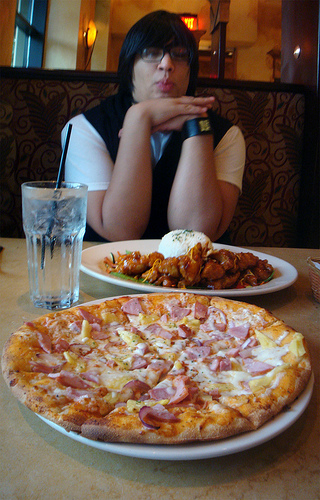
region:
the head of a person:
[119, 22, 229, 129]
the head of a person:
[110, 58, 192, 118]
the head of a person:
[128, 3, 196, 156]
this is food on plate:
[107, 234, 271, 286]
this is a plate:
[3, 293, 307, 468]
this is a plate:
[77, 230, 302, 293]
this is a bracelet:
[182, 115, 214, 140]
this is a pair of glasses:
[137, 38, 200, 64]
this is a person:
[64, 1, 245, 248]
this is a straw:
[52, 126, 78, 187]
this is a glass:
[20, 179, 88, 304]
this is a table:
[0, 241, 316, 497]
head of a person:
[100, 6, 221, 121]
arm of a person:
[87, 97, 181, 226]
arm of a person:
[171, 117, 237, 206]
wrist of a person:
[113, 111, 167, 129]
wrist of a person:
[174, 105, 232, 143]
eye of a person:
[144, 43, 170, 66]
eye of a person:
[162, 25, 198, 67]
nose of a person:
[144, 56, 180, 82]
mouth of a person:
[155, 66, 181, 90]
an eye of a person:
[134, 39, 163, 67]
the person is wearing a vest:
[85, 91, 226, 243]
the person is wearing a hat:
[114, 8, 204, 64]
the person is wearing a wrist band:
[180, 113, 211, 139]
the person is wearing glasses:
[141, 43, 192, 62]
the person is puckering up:
[150, 75, 177, 92]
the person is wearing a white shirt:
[55, 102, 245, 195]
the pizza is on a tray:
[5, 290, 308, 438]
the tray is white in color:
[16, 297, 317, 456]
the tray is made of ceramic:
[23, 292, 311, 461]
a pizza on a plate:
[8, 274, 309, 471]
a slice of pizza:
[77, 361, 253, 452]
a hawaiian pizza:
[7, 295, 311, 464]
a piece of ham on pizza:
[133, 375, 187, 433]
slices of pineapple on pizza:
[77, 317, 150, 369]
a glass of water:
[11, 167, 101, 311]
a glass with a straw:
[10, 109, 102, 315]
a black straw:
[29, 114, 80, 280]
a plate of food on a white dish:
[71, 218, 306, 303]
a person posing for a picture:
[46, 10, 259, 242]